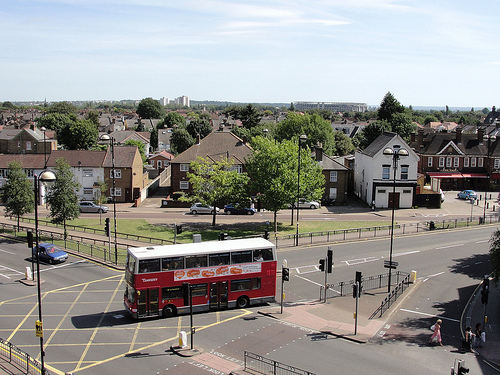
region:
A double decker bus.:
[115, 234, 291, 330]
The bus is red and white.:
[114, 234, 285, 323]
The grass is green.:
[133, 225, 169, 238]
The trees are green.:
[193, 132, 309, 215]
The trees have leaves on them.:
[193, 135, 315, 210]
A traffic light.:
[316, 245, 338, 284]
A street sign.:
[380, 257, 403, 275]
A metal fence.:
[238, 345, 324, 373]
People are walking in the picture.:
[421, 305, 498, 372]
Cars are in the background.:
[58, 190, 276, 225]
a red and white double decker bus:
[121, 236, 278, 319]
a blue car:
[29, 242, 68, 265]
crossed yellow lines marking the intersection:
[1, 272, 253, 371]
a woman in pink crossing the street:
[427, 318, 447, 348]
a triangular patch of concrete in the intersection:
[258, 268, 420, 343]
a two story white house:
[353, 132, 423, 212]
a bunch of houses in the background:
[0, 100, 498, 215]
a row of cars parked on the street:
[64, 195, 321, 215]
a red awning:
[427, 169, 492, 180]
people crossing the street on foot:
[428, 316, 487, 352]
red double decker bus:
[116, 240, 283, 318]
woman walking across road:
[414, 304, 448, 346]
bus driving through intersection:
[118, 243, 284, 314]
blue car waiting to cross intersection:
[23, 242, 70, 267]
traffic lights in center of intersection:
[273, 249, 371, 329]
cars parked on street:
[76, 194, 273, 224]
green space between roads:
[17, 210, 406, 256]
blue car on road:
[31, 238, 68, 272]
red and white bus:
[115, 238, 282, 318]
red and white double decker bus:
[120, 243, 288, 313]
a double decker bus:
[124, 231, 281, 319]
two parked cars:
[186, 199, 261, 219]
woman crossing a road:
[427, 315, 449, 347]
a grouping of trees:
[180, 147, 311, 225]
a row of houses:
[2, 148, 147, 205]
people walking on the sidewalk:
[460, 320, 495, 362]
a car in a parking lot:
[448, 186, 488, 213]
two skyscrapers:
[158, 96, 193, 109]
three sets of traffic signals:
[272, 242, 374, 323]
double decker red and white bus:
[86, 237, 311, 335]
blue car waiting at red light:
[19, 224, 75, 312]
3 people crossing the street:
[417, 290, 493, 370]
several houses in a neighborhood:
[93, 117, 465, 202]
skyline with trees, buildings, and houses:
[88, 89, 482, 128]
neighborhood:
[143, 118, 429, 230]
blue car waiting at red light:
[17, 214, 114, 332]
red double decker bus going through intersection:
[119, 236, 336, 336]